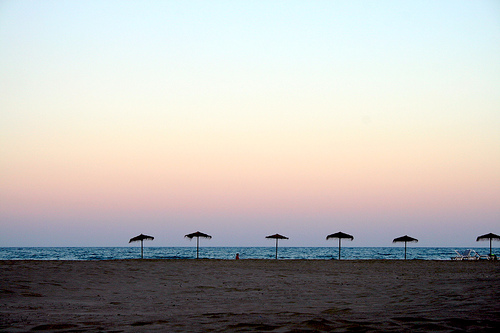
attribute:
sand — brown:
[1, 256, 499, 331]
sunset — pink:
[78, 84, 495, 269]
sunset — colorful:
[0, 0, 499, 248]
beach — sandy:
[24, 257, 499, 326]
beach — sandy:
[0, 261, 496, 329]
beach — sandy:
[4, 255, 499, 320]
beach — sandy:
[300, 275, 374, 297]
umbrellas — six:
[385, 233, 422, 266]